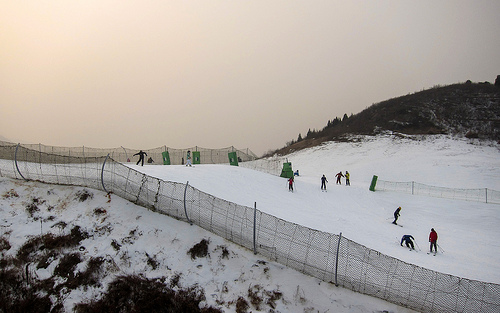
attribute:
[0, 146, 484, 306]
fecne — part 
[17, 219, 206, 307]
plants —  background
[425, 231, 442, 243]
jacket — red 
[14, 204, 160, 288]
plants — black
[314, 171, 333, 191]
outfit — black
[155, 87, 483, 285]
hill — white , Brown 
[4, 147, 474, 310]
fence — darkest net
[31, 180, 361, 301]
fence — past 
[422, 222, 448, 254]
person — Very dark 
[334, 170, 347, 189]
arms — out 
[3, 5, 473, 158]
sky — grey 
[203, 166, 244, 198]
snow — White 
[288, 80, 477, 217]
hill — brown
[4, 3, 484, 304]
picture — top 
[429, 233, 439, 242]
coat — red 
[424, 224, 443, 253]
person — Red coat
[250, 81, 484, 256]
hill — down 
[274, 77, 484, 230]
hill — Blue coat , bottom 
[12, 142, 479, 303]
landscape — snowy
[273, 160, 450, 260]
skier — falling down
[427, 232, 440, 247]
suit — red ski 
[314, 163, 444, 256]
skier — skiing downhill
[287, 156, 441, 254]
people — arms out.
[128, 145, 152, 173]
person — on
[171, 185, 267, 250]
fence — enclosing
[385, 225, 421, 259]
person — in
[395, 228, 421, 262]
person — in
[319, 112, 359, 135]
trees — on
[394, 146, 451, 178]
snow — on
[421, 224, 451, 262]
person — in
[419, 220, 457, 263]
person — in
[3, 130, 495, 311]
snow — smooth, white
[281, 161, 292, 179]
sign — green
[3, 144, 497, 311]
net — long